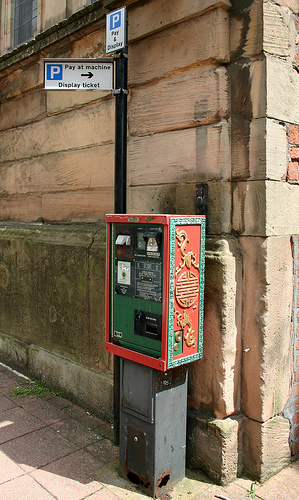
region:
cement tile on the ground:
[19, 435, 65, 462]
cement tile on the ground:
[1, 413, 39, 432]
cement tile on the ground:
[11, 385, 29, 403]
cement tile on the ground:
[62, 417, 88, 438]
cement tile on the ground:
[271, 472, 295, 496]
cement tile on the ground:
[95, 444, 112, 459]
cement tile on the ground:
[4, 479, 43, 498]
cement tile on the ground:
[1, 463, 15, 473]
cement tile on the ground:
[45, 454, 94, 488]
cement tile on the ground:
[93, 440, 110, 455]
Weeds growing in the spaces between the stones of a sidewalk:
[8, 379, 64, 401]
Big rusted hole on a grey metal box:
[152, 468, 173, 497]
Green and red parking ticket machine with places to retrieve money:
[102, 212, 204, 372]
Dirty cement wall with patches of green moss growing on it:
[0, 221, 115, 423]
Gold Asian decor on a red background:
[172, 226, 198, 348]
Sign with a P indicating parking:
[42, 57, 115, 90]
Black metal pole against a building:
[110, 5, 129, 445]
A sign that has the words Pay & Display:
[105, 5, 126, 54]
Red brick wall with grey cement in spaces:
[281, 232, 298, 467]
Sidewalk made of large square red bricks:
[0, 361, 298, 499]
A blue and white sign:
[38, 54, 131, 102]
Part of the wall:
[265, 318, 280, 340]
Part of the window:
[17, 9, 33, 22]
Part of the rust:
[155, 487, 162, 492]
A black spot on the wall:
[194, 179, 209, 217]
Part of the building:
[43, 4, 61, 12]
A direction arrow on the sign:
[78, 69, 94, 78]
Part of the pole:
[113, 137, 130, 167]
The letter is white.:
[48, 65, 60, 79]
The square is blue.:
[45, 63, 63, 81]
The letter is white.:
[110, 12, 118, 25]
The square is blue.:
[109, 11, 121, 27]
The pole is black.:
[109, 52, 139, 208]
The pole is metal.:
[112, 57, 138, 210]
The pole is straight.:
[108, 50, 138, 205]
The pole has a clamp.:
[108, 84, 132, 96]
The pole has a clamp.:
[110, 50, 128, 58]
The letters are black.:
[53, 80, 104, 91]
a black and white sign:
[37, 53, 124, 97]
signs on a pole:
[22, 4, 158, 208]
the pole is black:
[109, 56, 133, 210]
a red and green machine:
[94, 203, 211, 377]